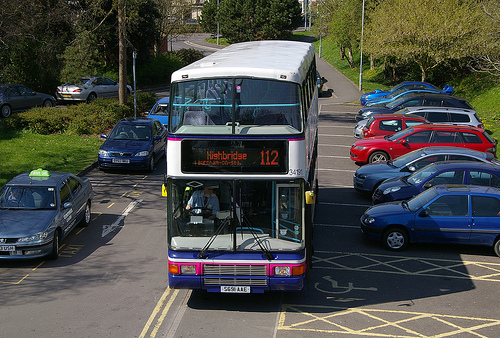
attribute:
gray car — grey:
[54, 75, 134, 102]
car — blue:
[366, 187, 498, 254]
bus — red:
[143, 15, 331, 306]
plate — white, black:
[218, 283, 253, 295]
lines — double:
[138, 285, 174, 337]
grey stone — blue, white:
[160, 31, 323, 312]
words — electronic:
[191, 147, 250, 171]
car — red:
[345, 122, 497, 167]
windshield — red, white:
[162, 176, 307, 263]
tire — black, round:
[379, 223, 413, 254]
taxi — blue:
[4, 164, 99, 267]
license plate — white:
[222, 281, 252, 294]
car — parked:
[4, 81, 54, 111]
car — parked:
[57, 67, 128, 101]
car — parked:
[102, 113, 166, 171]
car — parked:
[4, 166, 92, 260]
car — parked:
[360, 185, 484, 246]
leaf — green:
[217, 11, 225, 18]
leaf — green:
[247, 4, 254, 10]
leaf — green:
[234, 16, 244, 23]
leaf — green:
[276, 9, 281, 18]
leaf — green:
[210, 3, 216, 12]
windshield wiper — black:
[240, 212, 262, 249]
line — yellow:
[138, 301, 154, 336]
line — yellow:
[151, 313, 167, 336]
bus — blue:
[163, 36, 322, 296]